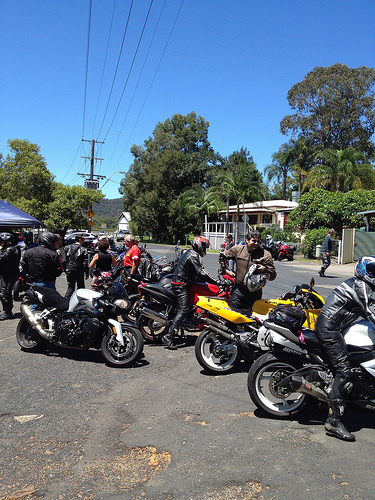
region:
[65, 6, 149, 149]
suspended power cables on a pole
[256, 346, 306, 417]
rear wheel of a motorcycle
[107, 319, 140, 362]
the front wheel of a motorcycle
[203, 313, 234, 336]
a metal exhaust pipe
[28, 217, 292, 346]
a gathering of bikers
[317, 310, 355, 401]
a person wearing black leather pants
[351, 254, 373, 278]
a white and blue helmet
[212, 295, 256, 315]
the seat on a motorcycle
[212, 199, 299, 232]
a white and red house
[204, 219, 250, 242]
the deck on a house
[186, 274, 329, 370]
yellow and black motorcycle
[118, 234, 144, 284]
man wearing red shirt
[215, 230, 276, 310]
man wearing brown shirt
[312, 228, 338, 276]
man walking down the street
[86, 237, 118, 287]
woman wearing black shirt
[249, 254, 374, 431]
rider sitting on motorcycle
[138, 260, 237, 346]
red and black motorcycle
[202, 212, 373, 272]
fencing along the sidewalk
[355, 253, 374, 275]
blue and white helmet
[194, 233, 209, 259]
red and silver helmet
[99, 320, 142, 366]
black tire on motorcycle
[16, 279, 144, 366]
motorcycle on street outside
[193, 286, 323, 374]
yellow motorcycle parked on street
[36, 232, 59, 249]
black motorcycle on head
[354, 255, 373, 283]
blue and white motorcycle helmet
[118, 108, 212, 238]
green trees in on street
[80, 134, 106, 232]
phone pole on street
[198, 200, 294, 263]
white house on side of street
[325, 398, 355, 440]
black motorcycle boot on man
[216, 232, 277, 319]
man wearing brown leather jacket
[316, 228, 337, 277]
man crossing the street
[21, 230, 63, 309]
man wearing a black helmet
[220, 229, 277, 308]
man holding a helment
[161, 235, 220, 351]
man riding a motorcycle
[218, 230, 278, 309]
man standing next to motorcycle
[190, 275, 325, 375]
yellow motorcycle parked on the street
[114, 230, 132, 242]
car in the distance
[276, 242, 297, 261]
red motorcycle parked on the other side of street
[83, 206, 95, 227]
traffic signs on the post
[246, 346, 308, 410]
tire on a cycle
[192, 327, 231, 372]
tire on a cycle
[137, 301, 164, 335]
tire on a cycle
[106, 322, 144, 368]
tire on a cycle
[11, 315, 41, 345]
tire on a cycle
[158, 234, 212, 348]
cyclist wearing a helmet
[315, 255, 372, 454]
cyclist wearing a helmet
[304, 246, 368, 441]
cyclist wearing black jacket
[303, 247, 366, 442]
cyclist wearing black boots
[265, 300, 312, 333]
bag on a cycle